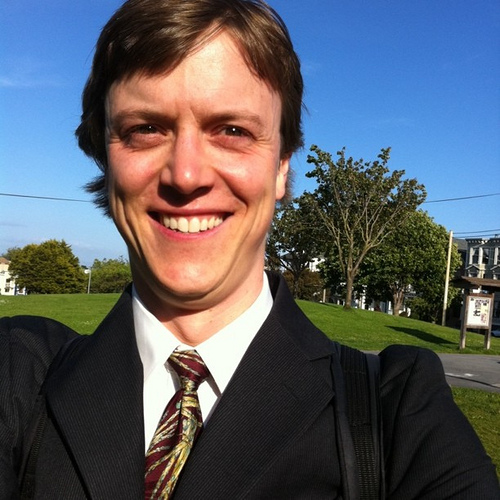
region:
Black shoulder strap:
[321, 314, 396, 499]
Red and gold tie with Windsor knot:
[140, 331, 206, 498]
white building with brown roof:
[0, 251, 27, 297]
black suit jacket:
[2, 306, 482, 497]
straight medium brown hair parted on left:
[67, 0, 312, 108]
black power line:
[0, 191, 86, 206]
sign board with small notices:
[460, 293, 496, 336]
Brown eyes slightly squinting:
[123, 110, 259, 145]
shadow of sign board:
[381, 315, 449, 345]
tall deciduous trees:
[308, 149, 425, 307]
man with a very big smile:
[12, 10, 454, 461]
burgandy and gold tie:
[125, 325, 260, 493]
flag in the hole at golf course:
[33, 242, 118, 302]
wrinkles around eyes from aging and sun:
[87, 107, 330, 172]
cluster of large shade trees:
[280, 120, 466, 312]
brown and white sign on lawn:
[427, 274, 494, 344]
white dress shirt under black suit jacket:
[9, 269, 478, 450]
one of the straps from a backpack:
[286, 311, 415, 478]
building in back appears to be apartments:
[332, 216, 498, 317]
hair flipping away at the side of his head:
[17, 57, 147, 250]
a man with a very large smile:
[77, 33, 281, 292]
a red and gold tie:
[137, 333, 232, 498]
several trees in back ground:
[6, 222, 498, 282]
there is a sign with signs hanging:
[428, 257, 498, 355]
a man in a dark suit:
[10, 300, 498, 477]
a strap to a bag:
[325, 308, 416, 498]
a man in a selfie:
[33, 33, 380, 491]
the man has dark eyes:
[100, 90, 307, 152]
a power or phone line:
[7, 180, 498, 210]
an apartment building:
[360, 220, 497, 327]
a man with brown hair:
[66, 14, 331, 305]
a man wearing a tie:
[103, 32, 324, 469]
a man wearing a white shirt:
[70, 84, 306, 449]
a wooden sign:
[449, 267, 495, 355]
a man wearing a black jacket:
[105, 22, 297, 452]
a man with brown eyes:
[78, 25, 300, 177]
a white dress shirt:
[96, 255, 290, 436]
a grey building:
[446, 226, 497, 293]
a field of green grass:
[0, 283, 119, 329]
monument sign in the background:
[456, 291, 498, 348]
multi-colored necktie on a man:
[129, 343, 213, 496]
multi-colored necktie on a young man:
[135, 337, 216, 499]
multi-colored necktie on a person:
[129, 340, 214, 499]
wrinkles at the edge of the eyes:
[251, 115, 283, 162]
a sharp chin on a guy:
[137, 225, 244, 309]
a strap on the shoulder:
[336, 329, 391, 497]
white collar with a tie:
[111, 260, 290, 407]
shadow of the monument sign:
[375, 318, 458, 365]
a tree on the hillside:
[287, 137, 432, 316]